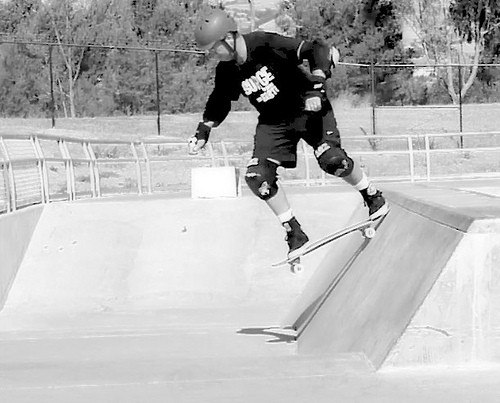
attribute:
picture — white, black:
[10, 19, 489, 282]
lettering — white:
[242, 75, 274, 105]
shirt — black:
[210, 61, 314, 121]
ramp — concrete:
[209, 222, 483, 365]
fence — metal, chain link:
[32, 45, 498, 150]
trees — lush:
[21, 7, 232, 97]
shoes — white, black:
[283, 223, 312, 248]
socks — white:
[279, 209, 298, 226]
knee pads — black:
[242, 158, 281, 206]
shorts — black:
[253, 115, 345, 157]